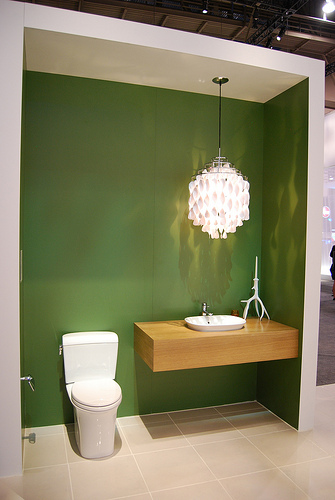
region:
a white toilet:
[62, 329, 128, 460]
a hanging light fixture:
[188, 78, 248, 240]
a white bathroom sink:
[186, 311, 245, 329]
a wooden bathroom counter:
[134, 310, 300, 371]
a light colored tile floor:
[2, 399, 333, 497]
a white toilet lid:
[69, 379, 120, 407]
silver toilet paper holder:
[24, 367, 39, 393]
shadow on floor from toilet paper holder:
[16, 426, 48, 450]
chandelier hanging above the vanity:
[162, 139, 249, 244]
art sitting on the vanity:
[243, 255, 274, 336]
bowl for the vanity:
[183, 311, 258, 327]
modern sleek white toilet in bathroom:
[47, 315, 131, 471]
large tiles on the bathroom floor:
[139, 419, 253, 488]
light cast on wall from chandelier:
[150, 191, 224, 300]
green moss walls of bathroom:
[45, 171, 151, 285]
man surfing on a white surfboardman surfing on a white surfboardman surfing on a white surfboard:
[210, 442, 249, 474]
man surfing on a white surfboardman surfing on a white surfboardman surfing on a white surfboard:
[217, 450, 228, 461]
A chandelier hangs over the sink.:
[186, 71, 255, 246]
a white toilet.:
[54, 326, 125, 459]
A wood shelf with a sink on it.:
[129, 313, 303, 376]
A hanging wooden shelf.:
[132, 306, 299, 413]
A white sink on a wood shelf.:
[184, 301, 249, 333]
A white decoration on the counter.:
[238, 252, 270, 320]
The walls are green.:
[20, 70, 311, 430]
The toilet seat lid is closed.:
[51, 324, 129, 461]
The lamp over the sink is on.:
[188, 72, 255, 243]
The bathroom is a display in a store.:
[13, 2, 325, 439]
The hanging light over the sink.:
[183, 72, 250, 235]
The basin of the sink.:
[184, 314, 245, 330]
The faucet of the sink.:
[203, 297, 211, 315]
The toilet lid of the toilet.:
[73, 376, 124, 405]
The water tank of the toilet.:
[63, 333, 117, 380]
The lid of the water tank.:
[61, 333, 116, 342]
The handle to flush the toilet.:
[57, 342, 61, 354]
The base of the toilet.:
[74, 404, 117, 458]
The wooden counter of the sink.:
[132, 325, 299, 370]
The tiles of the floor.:
[7, 383, 334, 499]